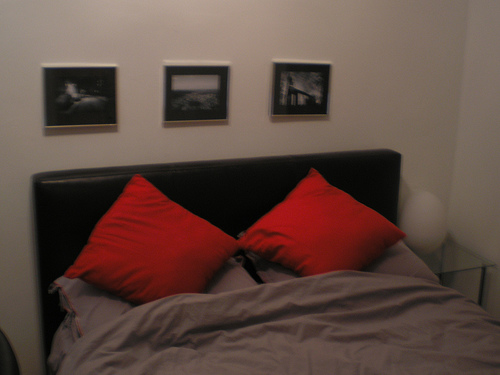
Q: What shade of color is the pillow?
A: Red.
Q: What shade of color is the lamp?
A: White.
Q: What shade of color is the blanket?
A: Gray.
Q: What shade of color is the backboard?
A: Black.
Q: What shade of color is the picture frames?
A: Gold.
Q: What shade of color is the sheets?
A: Gray.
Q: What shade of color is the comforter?
A: Gray.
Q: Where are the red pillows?
A: Bed.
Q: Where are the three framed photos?
A: Above bed.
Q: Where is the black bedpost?
A: Head of bed.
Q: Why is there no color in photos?
A: Black and white.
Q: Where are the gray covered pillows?
A: Under red pillows.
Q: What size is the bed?
A: Full.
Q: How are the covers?
A: Slightly wrinkled.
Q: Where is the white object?
A: Glass table.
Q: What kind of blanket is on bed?
A: Comforter.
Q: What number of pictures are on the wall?
A: Three.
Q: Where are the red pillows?
A: On the bed.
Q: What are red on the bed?
A: The pillows.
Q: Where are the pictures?
A: On the wall.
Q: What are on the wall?
A: Pictures.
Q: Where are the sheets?
A: Next to the pillows.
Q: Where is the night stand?
A: Next to the bed.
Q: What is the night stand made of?
A: Glass.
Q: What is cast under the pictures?
A: Shadows.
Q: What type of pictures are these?
A: Black and white.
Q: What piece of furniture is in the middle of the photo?
A: A bed.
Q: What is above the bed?
A: Three photos.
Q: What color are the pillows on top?
A: Red.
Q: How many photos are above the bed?
A: Three.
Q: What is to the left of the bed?
A: A nightstand.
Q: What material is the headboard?
A: Wood.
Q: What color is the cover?
A: Purple.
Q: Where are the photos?
A: Above the bed.